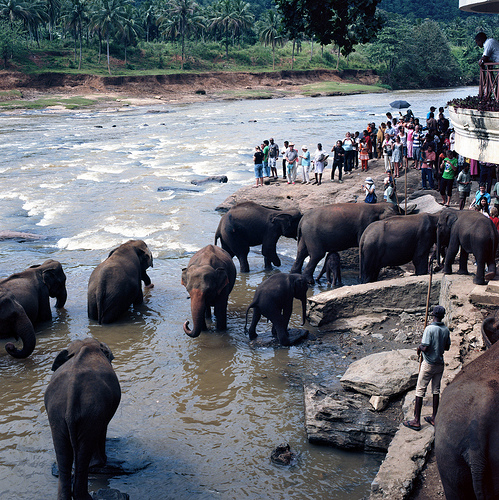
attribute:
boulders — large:
[315, 272, 483, 499]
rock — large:
[384, 96, 413, 116]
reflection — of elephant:
[179, 331, 241, 417]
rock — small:
[273, 441, 295, 466]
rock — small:
[143, 120, 148, 128]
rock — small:
[160, 120, 165, 126]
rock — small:
[95, 123, 102, 128]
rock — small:
[111, 121, 117, 128]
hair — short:
[427, 304, 447, 316]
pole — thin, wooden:
[417, 246, 437, 322]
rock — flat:
[316, 302, 476, 421]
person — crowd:
[313, 139, 330, 184]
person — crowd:
[297, 142, 314, 186]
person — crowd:
[331, 139, 343, 181]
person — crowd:
[380, 174, 394, 201]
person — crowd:
[355, 135, 371, 172]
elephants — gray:
[0, 194, 499, 499]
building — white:
[445, 1, 497, 167]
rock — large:
[324, 344, 438, 439]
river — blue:
[0, 85, 485, 497]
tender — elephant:
[401, 301, 453, 432]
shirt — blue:
[418, 324, 450, 362]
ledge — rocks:
[301, 303, 421, 448]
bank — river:
[248, 133, 447, 456]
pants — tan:
[406, 356, 445, 397]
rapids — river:
[41, 129, 348, 252]